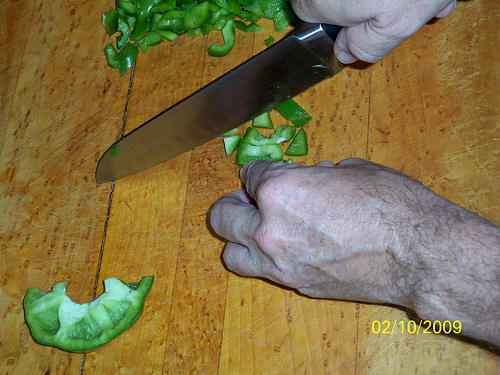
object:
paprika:
[101, 8, 118, 35]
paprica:
[117, 43, 139, 79]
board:
[0, 1, 499, 371]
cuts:
[98, 0, 295, 77]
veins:
[293, 240, 391, 267]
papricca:
[100, 44, 120, 72]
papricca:
[208, 19, 234, 59]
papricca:
[112, 19, 132, 49]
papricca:
[271, 8, 291, 32]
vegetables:
[219, 136, 243, 156]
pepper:
[200, 19, 216, 36]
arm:
[439, 194, 499, 347]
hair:
[355, 169, 499, 350]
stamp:
[370, 315, 475, 340]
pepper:
[260, 38, 274, 50]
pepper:
[270, 120, 295, 143]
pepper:
[282, 127, 308, 157]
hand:
[287, 0, 460, 65]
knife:
[93, 23, 338, 186]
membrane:
[57, 277, 124, 319]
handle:
[279, 21, 348, 78]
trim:
[308, 32, 343, 75]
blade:
[96, 39, 311, 185]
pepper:
[156, 30, 179, 42]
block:
[160, 12, 256, 374]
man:
[209, 1, 499, 346]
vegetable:
[273, 101, 312, 129]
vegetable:
[22, 273, 159, 354]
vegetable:
[137, 32, 162, 55]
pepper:
[233, 128, 285, 164]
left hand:
[208, 156, 443, 308]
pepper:
[116, 14, 131, 47]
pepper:
[151, 9, 181, 33]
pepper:
[182, 0, 210, 28]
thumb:
[331, 16, 421, 66]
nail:
[332, 47, 358, 65]